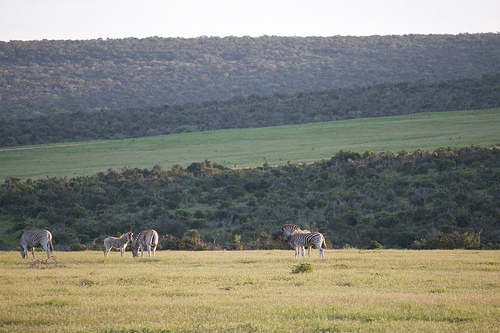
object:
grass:
[1, 247, 497, 331]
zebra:
[281, 223, 328, 259]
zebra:
[129, 229, 159, 258]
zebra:
[104, 231, 133, 257]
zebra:
[20, 228, 53, 259]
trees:
[0, 144, 499, 250]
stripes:
[295, 233, 322, 243]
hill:
[0, 32, 500, 145]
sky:
[0, 0, 499, 41]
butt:
[147, 229, 159, 242]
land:
[0, 108, 497, 184]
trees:
[0, 72, 497, 147]